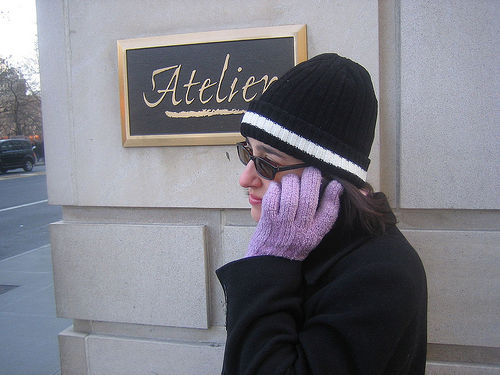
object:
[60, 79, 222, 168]
wall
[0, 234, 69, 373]
sidewalk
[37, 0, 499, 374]
building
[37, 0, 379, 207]
bricks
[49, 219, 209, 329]
bricks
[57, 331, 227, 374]
bricks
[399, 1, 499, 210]
bricks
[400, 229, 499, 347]
bricks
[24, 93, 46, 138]
tree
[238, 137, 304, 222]
face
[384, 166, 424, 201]
wall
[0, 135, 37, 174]
black car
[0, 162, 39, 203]
road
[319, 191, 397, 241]
collar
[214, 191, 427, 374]
black coat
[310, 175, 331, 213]
phone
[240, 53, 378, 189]
hat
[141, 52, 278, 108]
letters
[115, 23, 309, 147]
sign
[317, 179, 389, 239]
hair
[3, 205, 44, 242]
street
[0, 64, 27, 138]
trees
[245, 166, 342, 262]
glove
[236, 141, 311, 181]
glasses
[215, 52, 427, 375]
lady